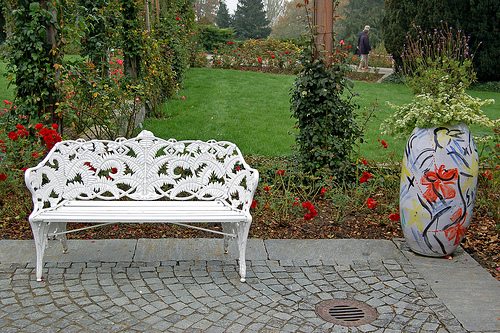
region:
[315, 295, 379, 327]
grey round metal storm drain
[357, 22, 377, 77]
man with grey hair and black jacket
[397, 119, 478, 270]
grey vase with red and yellow flowers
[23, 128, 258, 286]
white wrought iron bench with leaf design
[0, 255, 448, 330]
patio made of light grey brick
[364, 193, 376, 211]
bright red open rose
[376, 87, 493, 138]
light green variegated bush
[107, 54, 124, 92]
collection of bright pink roses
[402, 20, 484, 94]
tall green branches with bright purple flowers.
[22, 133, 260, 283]
THIS IS A WHITE BENCH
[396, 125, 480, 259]
THIS IS A FLOWER POT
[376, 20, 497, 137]
THIS IS A FLOWER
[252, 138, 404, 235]
THESE ARE RED ROSES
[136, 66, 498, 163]
THIS IS THE GREEN GRASS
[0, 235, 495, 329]
THIS IS A CONCRETE FLOOR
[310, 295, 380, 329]
THIS IS A WATER DRAIN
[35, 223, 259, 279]
THESE ARE THE LEGS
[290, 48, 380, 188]
THIS IS SHRUBBERY ON POLE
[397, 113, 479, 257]
a floral flower pot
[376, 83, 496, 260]
a flower in a pot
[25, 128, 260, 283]
a white iron bench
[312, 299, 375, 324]
a drain trap on the ground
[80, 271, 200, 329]
grays bricks on a walk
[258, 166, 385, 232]
red flowers on the ground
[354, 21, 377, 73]
a couple walking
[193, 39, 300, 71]
a line of flowers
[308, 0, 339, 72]
a wooden post with a vine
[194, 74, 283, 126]
a green grassy yard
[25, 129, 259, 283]
A white metal bench.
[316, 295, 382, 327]
A brown circular drain.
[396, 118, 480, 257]
A large colorful vase.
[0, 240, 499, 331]
A gray tiled patio.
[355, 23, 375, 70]
Two people taking a walk.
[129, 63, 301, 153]
A lush green lawn.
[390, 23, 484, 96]
A plant with purple flowers.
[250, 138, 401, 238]
An area of red flowers.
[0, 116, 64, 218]
A red rose bush.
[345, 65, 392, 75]
A cement walk way.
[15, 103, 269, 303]
a white bench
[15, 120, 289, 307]
a white bench on gray bricks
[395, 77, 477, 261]
a flower pot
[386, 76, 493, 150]
a plant growing in a flower pot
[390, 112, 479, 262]
a flower pot with prints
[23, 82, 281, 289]
a garden behind a bench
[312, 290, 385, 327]
a drainage hole on the ground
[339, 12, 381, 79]
two people walking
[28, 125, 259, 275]
a bench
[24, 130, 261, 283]
a white bench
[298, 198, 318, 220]
red flowers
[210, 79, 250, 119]
the lawn is green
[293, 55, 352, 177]
the leaves are green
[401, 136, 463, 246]
a design on the pot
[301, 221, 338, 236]
the dirt is brown